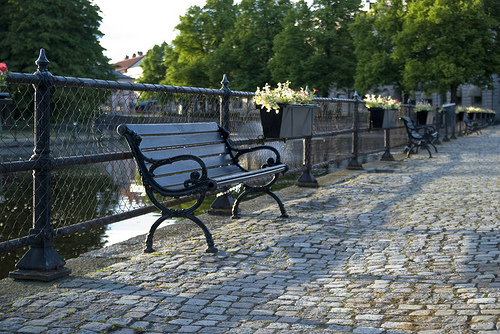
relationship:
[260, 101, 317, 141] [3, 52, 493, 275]
flower pot attached to fence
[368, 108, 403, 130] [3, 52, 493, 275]
flower pot attached to fence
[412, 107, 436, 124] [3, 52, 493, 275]
flower pot attached to fence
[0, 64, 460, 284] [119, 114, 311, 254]
fence behind bench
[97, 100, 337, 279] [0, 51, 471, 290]
bench near fence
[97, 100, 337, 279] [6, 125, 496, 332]
bench on walkaway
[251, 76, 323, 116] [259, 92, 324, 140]
plant on container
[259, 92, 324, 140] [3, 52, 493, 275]
container on fence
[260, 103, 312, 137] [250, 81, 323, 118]
container has plant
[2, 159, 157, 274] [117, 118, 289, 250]
river behind bench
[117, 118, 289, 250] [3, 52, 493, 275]
bench behind fence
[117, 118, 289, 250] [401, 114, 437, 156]
bench behind bench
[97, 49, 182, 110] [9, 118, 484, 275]
house across river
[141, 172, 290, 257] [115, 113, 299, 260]
legs supporting bench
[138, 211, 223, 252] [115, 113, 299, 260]
leg supporting bench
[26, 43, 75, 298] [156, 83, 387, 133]
post helping to support fence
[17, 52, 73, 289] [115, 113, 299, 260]
post closest to bench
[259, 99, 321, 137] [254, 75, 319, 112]
planter has flower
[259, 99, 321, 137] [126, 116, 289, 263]
planter right to bench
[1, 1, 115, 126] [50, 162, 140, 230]
tree by pond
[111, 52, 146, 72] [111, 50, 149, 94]
roof on building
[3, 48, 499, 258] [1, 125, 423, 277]
fence by pond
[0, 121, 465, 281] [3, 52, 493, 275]
pond behind fence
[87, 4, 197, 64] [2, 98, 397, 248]
sky over pond